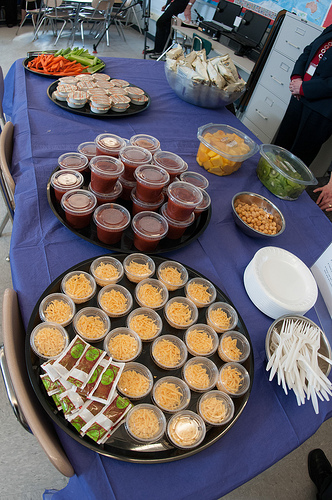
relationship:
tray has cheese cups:
[25, 251, 256, 464] [27, 252, 251, 452]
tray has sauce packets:
[25, 251, 256, 464] [40, 334, 133, 447]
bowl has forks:
[265, 312, 331, 383] [264, 317, 331, 416]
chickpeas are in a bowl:
[233, 197, 280, 235] [230, 190, 286, 241]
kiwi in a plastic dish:
[258, 154, 303, 200] [259, 143, 317, 201]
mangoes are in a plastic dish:
[195, 130, 250, 176] [196, 122, 258, 175]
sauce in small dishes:
[51, 130, 211, 255] [50, 130, 212, 254]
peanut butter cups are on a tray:
[55, 70, 147, 117] [46, 73, 151, 118]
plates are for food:
[243, 245, 318, 320] [25, 44, 308, 449]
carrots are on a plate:
[22, 53, 88, 74] [22, 51, 106, 76]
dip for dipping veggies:
[51, 72, 147, 116] [26, 47, 104, 77]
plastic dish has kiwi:
[259, 143, 317, 201] [258, 154, 303, 200]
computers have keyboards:
[199, 0, 272, 50] [200, 17, 258, 47]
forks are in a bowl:
[264, 317, 331, 416] [265, 312, 331, 383]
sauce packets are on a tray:
[40, 334, 133, 447] [25, 251, 256, 464]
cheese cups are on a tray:
[27, 252, 251, 452] [25, 251, 256, 464]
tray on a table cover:
[25, 251, 256, 464] [1, 50, 330, 497]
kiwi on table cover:
[258, 154, 303, 200] [1, 50, 330, 497]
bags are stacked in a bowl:
[164, 43, 248, 107] [164, 58, 248, 106]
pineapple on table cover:
[195, 130, 250, 176] [1, 50, 330, 497]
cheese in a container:
[130, 314, 157, 337] [128, 306, 162, 339]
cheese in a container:
[153, 340, 181, 366] [153, 336, 189, 368]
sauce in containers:
[51, 130, 211, 255] [50, 130, 212, 254]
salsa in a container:
[90, 160, 119, 191] [90, 154, 125, 193]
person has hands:
[270, 24, 331, 163] [289, 79, 303, 95]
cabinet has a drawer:
[240, 10, 329, 147] [272, 11, 322, 62]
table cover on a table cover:
[1, 50, 330, 497] [1, 50, 330, 497]